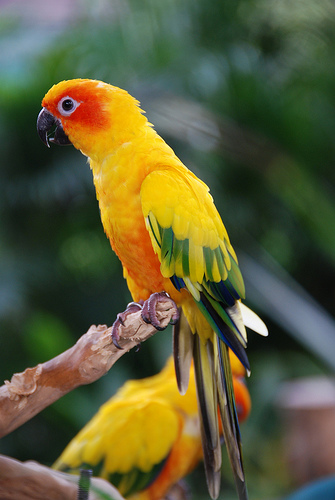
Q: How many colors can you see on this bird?
A: Five.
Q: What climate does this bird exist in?
A: Tropical.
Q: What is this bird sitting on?
A: A branch.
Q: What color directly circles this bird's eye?
A: Red.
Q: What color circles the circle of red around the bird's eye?
A: Orange.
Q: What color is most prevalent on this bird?
A: Yellow.